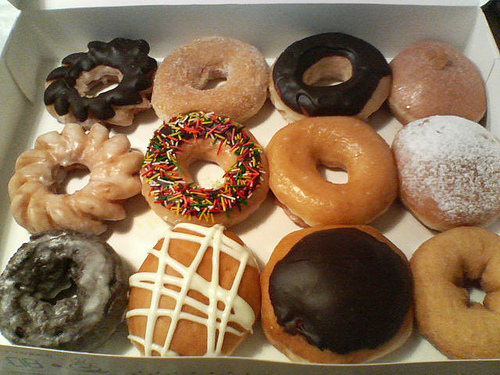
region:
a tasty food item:
[12, 126, 136, 228]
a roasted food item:
[278, 232, 410, 349]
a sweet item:
[399, 122, 496, 217]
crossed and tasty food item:
[132, 228, 244, 362]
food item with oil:
[270, 117, 393, 218]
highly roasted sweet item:
[50, 40, 172, 125]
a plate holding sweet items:
[6, 8, 499, 365]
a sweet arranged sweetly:
[141, 107, 253, 214]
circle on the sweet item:
[314, 160, 354, 188]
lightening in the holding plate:
[286, 5, 399, 42]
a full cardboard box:
[1, 3, 495, 368]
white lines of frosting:
[120, 249, 253, 329]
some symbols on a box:
[4, 351, 123, 373]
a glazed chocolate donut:
[0, 177, 132, 358]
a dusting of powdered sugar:
[408, 115, 494, 205]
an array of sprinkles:
[141, 177, 266, 219]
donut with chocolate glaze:
[263, 227, 418, 356]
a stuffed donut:
[376, 9, 485, 127]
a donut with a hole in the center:
[255, 122, 395, 223]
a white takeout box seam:
[1, 12, 50, 102]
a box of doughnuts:
[17, 12, 496, 368]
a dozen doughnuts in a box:
[8, 32, 498, 373]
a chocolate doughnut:
[271, 35, 391, 117]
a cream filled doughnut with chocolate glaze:
[266, 231, 413, 357]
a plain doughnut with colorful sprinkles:
[146, 116, 263, 220]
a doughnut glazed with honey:
[271, 117, 399, 226]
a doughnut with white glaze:
[131, 224, 261, 366]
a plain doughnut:
[406, 237, 497, 372]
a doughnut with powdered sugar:
[396, 112, 498, 224]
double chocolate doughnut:
[0, 232, 122, 344]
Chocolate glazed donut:
[266, 224, 413, 361]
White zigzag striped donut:
[136, 226, 257, 357]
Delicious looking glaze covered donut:
[3, 229, 129, 348]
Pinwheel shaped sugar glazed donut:
[6, 122, 143, 232]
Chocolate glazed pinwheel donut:
[48, 37, 154, 128]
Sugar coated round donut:
[154, 37, 267, 119]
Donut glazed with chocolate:
[270, 33, 390, 121]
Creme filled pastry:
[390, 40, 487, 122]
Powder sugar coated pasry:
[393, 115, 498, 227]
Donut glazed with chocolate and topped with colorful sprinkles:
[143, 111, 271, 222]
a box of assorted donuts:
[1, 5, 497, 368]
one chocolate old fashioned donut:
[1, 233, 126, 350]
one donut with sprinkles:
[145, 106, 273, 226]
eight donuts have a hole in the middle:
[8, 10, 498, 362]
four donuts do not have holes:
[131, 27, 496, 357]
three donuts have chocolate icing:
[14, 10, 418, 354]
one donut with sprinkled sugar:
[394, 110, 498, 227]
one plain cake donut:
[411, 229, 499, 361]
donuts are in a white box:
[3, 4, 495, 373]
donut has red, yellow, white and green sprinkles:
[141, 107, 276, 228]